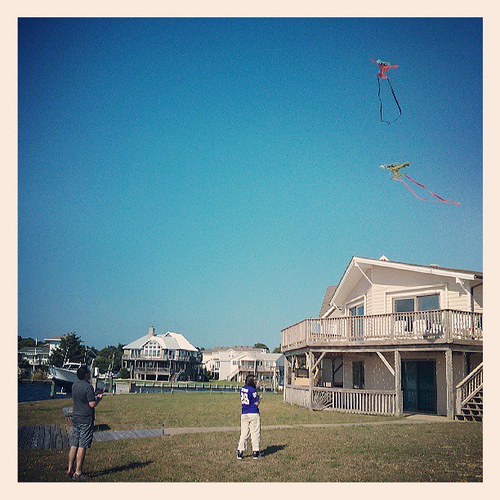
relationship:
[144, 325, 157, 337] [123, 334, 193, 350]
chimney on roof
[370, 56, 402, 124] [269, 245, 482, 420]
kite over house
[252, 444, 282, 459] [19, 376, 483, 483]
shadow on ground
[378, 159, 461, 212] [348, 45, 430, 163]
kite in air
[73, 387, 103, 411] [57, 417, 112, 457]
shirt with shorts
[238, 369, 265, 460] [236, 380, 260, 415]
people wearing jersey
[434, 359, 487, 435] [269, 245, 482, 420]
stairs on house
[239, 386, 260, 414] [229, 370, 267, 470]
blue shirt on woman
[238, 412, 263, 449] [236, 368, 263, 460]
gray pants on woman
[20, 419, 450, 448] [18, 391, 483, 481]
sidewalk through yard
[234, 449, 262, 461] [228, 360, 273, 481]
sneakers on woman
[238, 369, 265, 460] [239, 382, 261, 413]
people wearing blue shirt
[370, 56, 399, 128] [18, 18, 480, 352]
kite in sky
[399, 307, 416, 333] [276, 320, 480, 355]
chair on deck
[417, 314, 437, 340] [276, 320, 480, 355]
chair on deck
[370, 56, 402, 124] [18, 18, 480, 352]
kite in sky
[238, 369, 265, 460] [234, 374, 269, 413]
people wearing blue shirt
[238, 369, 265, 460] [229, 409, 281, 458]
people wearing gray pants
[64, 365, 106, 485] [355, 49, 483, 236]
guy flying kites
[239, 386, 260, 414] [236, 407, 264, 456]
blue shirt and pants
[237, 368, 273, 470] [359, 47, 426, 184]
people flying kite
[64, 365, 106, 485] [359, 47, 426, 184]
guy flying kite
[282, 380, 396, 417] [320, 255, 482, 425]
fence on house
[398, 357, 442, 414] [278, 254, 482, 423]
sliding door on house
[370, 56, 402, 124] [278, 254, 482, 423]
kite over house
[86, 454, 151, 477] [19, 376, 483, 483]
shadow on ground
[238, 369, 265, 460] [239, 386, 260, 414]
people wearing blue shirt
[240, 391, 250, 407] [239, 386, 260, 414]
numbers on blue shirt